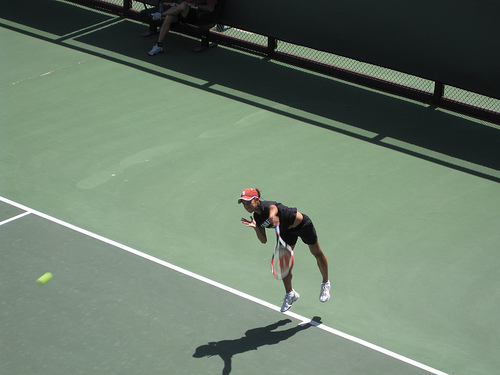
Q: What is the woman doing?
A: Playing tennis.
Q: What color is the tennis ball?
A: Yellowish green.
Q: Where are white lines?
A: On the court.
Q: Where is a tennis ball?
A: In the air.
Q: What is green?
A: The court.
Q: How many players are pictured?
A: One.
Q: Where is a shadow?
A: On court.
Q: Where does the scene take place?
A: At a tennis game.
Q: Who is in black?
A: Tennis player.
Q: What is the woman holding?
A: Racket.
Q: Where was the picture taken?
A: On a tennis court.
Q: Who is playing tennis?
A: A woman.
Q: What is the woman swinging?
A: A racket.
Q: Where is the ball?
A: In the air.